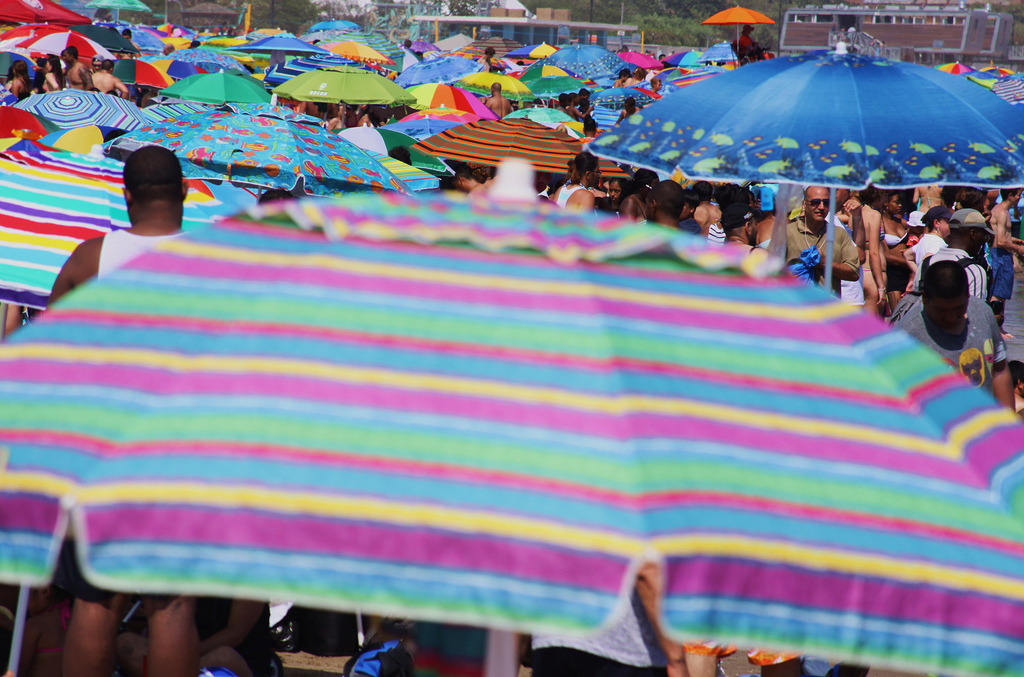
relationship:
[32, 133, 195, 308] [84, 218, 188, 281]
man wears shirt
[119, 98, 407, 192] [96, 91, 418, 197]
fish pattern printed on umbrella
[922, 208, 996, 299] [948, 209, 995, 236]
man wearing a ball cap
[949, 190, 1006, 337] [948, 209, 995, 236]
man wearing ball cap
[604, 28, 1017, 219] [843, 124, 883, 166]
blue umbrella with light green fish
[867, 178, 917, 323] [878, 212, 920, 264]
woman wearing white bikini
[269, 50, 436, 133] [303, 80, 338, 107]
green umbrella with white logo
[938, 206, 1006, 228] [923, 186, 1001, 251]
ball cap on man's head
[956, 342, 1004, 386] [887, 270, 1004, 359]
luchadore face on man's t-shirt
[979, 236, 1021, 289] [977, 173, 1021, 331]
board shorts on young man